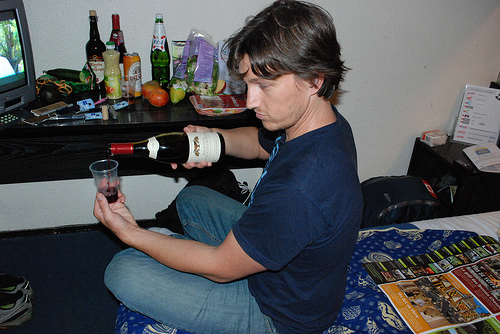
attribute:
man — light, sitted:
[85, 3, 358, 333]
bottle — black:
[105, 129, 226, 163]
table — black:
[0, 68, 319, 181]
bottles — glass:
[83, 9, 175, 100]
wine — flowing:
[97, 154, 120, 204]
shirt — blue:
[230, 122, 360, 332]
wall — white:
[1, 0, 499, 228]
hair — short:
[222, 2, 350, 99]